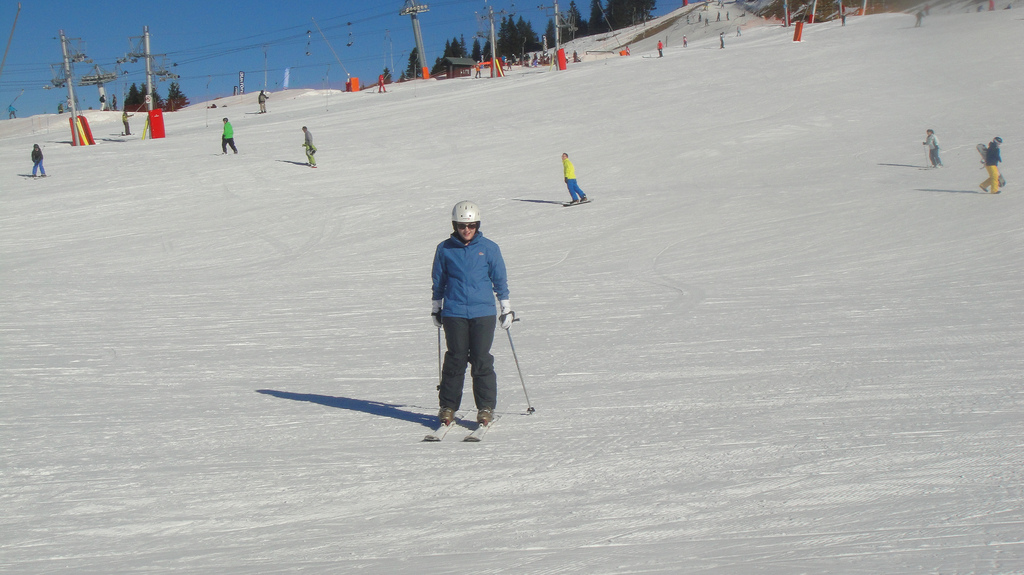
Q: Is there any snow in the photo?
A: Yes, there is snow.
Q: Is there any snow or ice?
A: Yes, there is snow.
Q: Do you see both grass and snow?
A: No, there is snow but no grass.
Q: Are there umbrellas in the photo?
A: No, there are no umbrellas.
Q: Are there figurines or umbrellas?
A: No, there are no umbrellas or figurines.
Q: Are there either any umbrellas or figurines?
A: No, there are no umbrellas or figurines.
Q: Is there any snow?
A: Yes, there is snow.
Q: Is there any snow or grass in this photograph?
A: Yes, there is snow.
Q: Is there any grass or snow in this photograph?
A: Yes, there is snow.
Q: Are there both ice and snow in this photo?
A: No, there is snow but no ice.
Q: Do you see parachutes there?
A: No, there are no parachutes.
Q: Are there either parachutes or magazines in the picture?
A: No, there are no parachutes or magazines.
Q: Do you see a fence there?
A: No, there are no fences.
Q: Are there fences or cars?
A: No, there are no fences or cars.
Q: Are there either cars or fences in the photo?
A: No, there are no fences or cars.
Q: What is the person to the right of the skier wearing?
A: The person is wearing trousers.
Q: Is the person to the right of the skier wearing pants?
A: Yes, the person is wearing pants.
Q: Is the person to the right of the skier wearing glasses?
A: No, the person is wearing pants.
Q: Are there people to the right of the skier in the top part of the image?
A: Yes, there is a person to the right of the skier.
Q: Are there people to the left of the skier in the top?
A: No, the person is to the right of the skier.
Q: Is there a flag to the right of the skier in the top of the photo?
A: No, there is a person to the right of the skier.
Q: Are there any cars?
A: No, there are no cars.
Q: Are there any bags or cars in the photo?
A: No, there are no cars or bags.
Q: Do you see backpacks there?
A: No, there are no backpacks.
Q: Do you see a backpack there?
A: No, there are no backpacks.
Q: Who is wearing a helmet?
A: The skier is wearing a helmet.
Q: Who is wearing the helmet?
A: The skier is wearing a helmet.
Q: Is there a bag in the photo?
A: No, there are no bags.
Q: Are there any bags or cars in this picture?
A: No, there are no bags or cars.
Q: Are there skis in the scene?
A: Yes, there are skis.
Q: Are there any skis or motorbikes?
A: Yes, there are skis.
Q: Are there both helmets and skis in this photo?
A: Yes, there are both skis and a helmet.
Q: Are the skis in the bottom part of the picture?
A: Yes, the skis are in the bottom of the image.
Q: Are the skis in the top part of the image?
A: No, the skis are in the bottom of the image.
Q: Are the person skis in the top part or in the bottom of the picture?
A: The skis are in the bottom of the image.